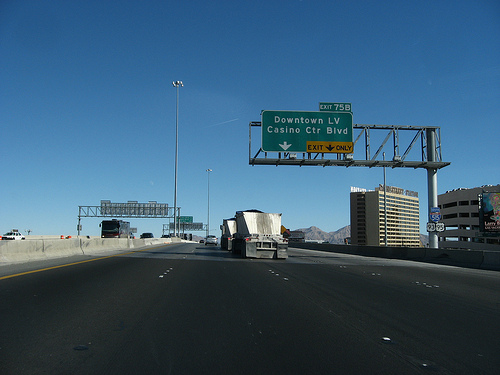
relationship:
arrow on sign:
[275, 135, 292, 151] [260, 97, 355, 152]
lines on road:
[146, 249, 220, 294] [2, 240, 498, 372]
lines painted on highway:
[153, 261, 175, 285] [1, 239, 496, 374]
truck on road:
[232, 210, 289, 257] [2, 240, 498, 372]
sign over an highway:
[262, 102, 352, 154] [1, 239, 496, 374]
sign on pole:
[262, 108, 352, 154] [425, 124, 442, 256]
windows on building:
[437, 199, 479, 214] [428, 182, 497, 249]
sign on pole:
[429, 204, 444, 222] [424, 124, 447, 252]